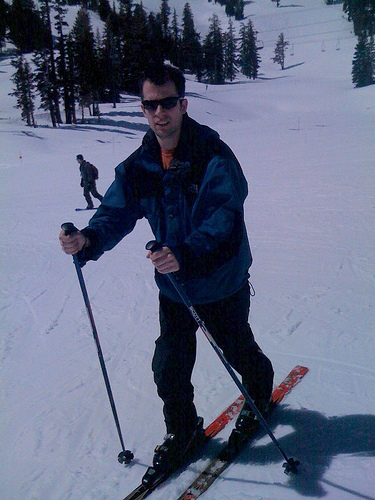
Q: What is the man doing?
A: Skiing.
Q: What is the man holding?
A: Ski poles.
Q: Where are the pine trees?
A: Background.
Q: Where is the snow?
A: On ground.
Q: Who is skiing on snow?
A: A man.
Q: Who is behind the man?
A: Another skier.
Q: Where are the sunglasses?
A: On man.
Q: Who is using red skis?
A: The man.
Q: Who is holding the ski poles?
A: The skier.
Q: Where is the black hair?
A: On man's head.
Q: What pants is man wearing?
A: Black.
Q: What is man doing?
A: Skiing.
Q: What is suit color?
A: Blue.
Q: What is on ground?
A: Snow.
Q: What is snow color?
A: White.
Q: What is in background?
A: Tree.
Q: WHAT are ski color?
A: Red.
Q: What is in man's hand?
A: Ski pole.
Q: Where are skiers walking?
A: In the snow.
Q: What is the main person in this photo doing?
A: Skiing.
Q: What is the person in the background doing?
A: Snowboarding.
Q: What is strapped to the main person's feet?
A: Skis.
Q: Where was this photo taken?
A: Outside, in the snow.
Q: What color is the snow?
A: White.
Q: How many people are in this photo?
A: Two.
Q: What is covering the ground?
A: Snow.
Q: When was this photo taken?
A: During the winter months.